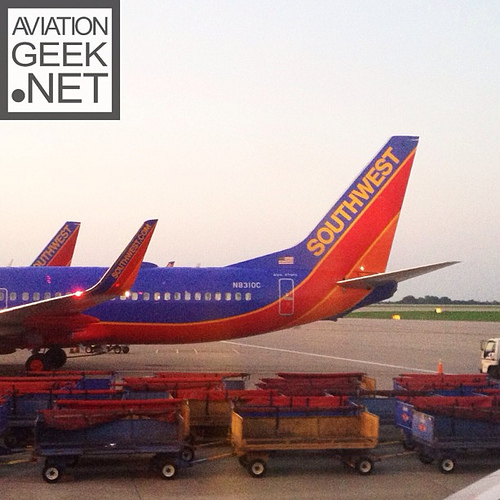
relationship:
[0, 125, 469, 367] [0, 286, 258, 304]
airplane has windows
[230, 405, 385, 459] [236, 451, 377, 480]
cart has wheels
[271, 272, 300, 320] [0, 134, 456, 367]
door on plane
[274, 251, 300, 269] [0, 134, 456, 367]
flag on plane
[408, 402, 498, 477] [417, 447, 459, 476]
cart has wheels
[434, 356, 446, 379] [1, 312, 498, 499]
cone on runway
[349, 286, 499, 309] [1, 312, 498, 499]
trees on runway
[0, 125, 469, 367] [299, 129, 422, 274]
airplane has tailfin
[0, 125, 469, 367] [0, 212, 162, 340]
airplane has wings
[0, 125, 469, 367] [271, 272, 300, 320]
airplane has door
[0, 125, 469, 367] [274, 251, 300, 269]
airplane has flag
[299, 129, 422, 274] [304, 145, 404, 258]
tailfin has word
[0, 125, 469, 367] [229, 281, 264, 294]
airplane has number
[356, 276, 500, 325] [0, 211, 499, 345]
forest in distance